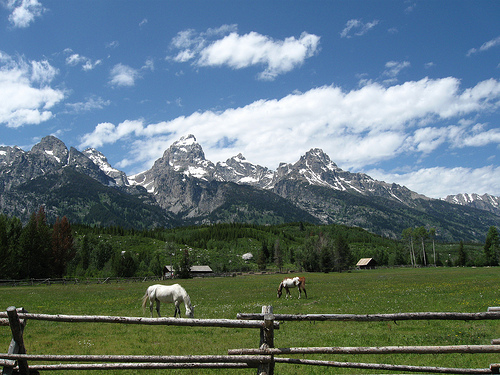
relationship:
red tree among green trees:
[52, 213, 79, 260] [0, 209, 42, 279]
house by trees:
[163, 261, 230, 275] [14, 208, 498, 277]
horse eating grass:
[141, 284, 196, 317] [3, 271, 493, 358]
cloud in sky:
[174, 24, 323, 81] [4, 0, 497, 202]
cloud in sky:
[341, 17, 380, 38] [9, 7, 496, 133]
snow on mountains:
[187, 166, 204, 177] [0, 126, 498, 229]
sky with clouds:
[4, 0, 497, 202] [1, 1, 498, 187]